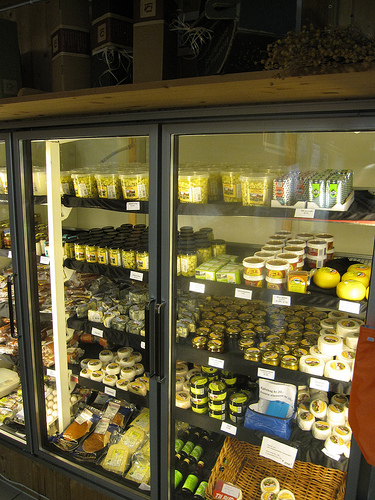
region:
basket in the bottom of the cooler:
[219, 439, 279, 494]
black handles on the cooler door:
[142, 295, 165, 385]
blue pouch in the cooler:
[244, 379, 299, 442]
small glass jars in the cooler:
[72, 232, 140, 269]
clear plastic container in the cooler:
[72, 171, 153, 207]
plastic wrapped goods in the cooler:
[106, 428, 152, 480]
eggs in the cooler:
[44, 396, 61, 423]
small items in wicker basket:
[251, 471, 285, 499]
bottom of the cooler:
[12, 450, 75, 497]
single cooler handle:
[3, 266, 24, 334]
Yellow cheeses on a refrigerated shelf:
[337, 261, 362, 296]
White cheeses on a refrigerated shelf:
[318, 315, 352, 378]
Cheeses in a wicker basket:
[253, 472, 300, 498]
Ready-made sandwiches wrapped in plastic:
[58, 411, 118, 460]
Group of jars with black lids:
[77, 227, 147, 261]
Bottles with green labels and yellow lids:
[175, 429, 209, 493]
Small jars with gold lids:
[200, 310, 320, 355]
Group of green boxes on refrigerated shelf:
[197, 253, 241, 284]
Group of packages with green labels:
[306, 167, 351, 213]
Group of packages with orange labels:
[272, 167, 313, 202]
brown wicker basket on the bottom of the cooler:
[218, 445, 295, 498]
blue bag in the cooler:
[241, 388, 295, 439]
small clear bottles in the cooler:
[79, 237, 142, 272]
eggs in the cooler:
[40, 385, 64, 421]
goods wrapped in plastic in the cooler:
[109, 418, 147, 488]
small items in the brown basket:
[246, 472, 282, 497]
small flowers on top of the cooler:
[265, 19, 371, 84]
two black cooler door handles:
[137, 298, 172, 388]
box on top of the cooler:
[132, 2, 174, 85]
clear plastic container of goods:
[69, 163, 146, 202]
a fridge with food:
[41, 91, 370, 452]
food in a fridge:
[46, 70, 322, 496]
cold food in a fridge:
[18, 104, 252, 492]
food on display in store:
[46, 92, 374, 412]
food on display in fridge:
[7, 69, 367, 495]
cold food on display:
[37, 119, 371, 474]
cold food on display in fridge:
[22, 119, 371, 458]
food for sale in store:
[36, 128, 317, 484]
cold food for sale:
[43, 108, 363, 493]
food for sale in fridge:
[4, 105, 374, 474]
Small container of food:
[235, 162, 279, 225]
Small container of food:
[176, 165, 211, 212]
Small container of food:
[113, 165, 139, 211]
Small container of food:
[92, 162, 135, 204]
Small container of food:
[63, 170, 99, 201]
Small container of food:
[175, 245, 201, 284]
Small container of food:
[134, 246, 149, 277]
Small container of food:
[118, 244, 130, 277]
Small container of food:
[105, 238, 120, 271]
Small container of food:
[82, 238, 109, 271]